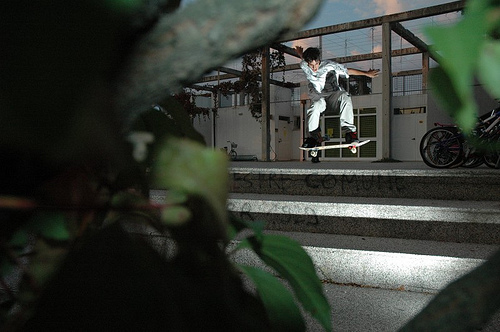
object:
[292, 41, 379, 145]
boy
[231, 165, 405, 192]
graffiti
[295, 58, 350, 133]
clothes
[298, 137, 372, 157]
board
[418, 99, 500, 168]
bikes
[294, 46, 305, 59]
hand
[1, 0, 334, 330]
plant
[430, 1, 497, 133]
plant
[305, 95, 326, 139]
leg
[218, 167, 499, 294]
gray stairs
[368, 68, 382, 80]
hand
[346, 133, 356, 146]
shoe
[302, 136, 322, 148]
shoe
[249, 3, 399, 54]
fencing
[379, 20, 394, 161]
metal pole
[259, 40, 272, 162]
metal pole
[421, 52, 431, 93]
metal pole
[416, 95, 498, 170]
motorcycle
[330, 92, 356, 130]
leg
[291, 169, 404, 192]
writing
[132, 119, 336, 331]
leaves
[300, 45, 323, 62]
hair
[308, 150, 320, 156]
wheels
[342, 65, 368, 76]
arms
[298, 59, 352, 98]
shirt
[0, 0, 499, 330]
outside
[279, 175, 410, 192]
commune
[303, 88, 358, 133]
pants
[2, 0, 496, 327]
picture